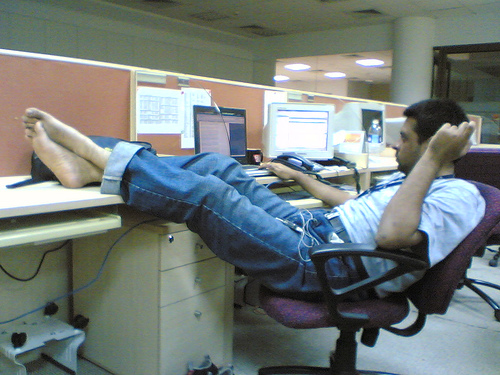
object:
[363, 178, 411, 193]
lanyard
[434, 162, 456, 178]
neck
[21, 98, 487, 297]
man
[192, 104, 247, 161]
monitor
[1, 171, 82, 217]
table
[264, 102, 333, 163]
monitor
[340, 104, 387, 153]
monitor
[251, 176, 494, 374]
chair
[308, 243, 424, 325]
armrest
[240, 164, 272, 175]
keyboard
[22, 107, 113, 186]
foot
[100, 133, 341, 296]
jeans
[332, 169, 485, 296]
shirt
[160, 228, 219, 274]
drawer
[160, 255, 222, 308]
drawer